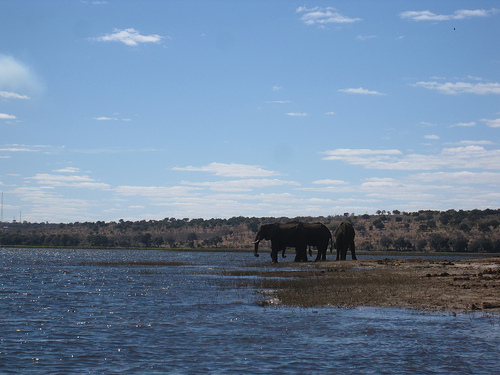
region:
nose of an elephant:
[249, 238, 264, 267]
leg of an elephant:
[263, 242, 280, 267]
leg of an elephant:
[288, 244, 315, 264]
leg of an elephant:
[308, 240, 333, 268]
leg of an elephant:
[334, 244, 354, 259]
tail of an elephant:
[322, 227, 342, 254]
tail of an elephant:
[306, 247, 316, 257]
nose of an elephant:
[329, 238, 337, 261]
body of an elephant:
[309, 212, 339, 250]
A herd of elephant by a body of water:
[235, 210, 362, 275]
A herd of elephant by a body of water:
[247, 216, 359, 271]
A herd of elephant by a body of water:
[240, 210, 359, 269]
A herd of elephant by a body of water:
[242, 212, 365, 272]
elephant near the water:
[233, 193, 352, 277]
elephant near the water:
[248, 205, 350, 275]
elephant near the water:
[241, 199, 368, 267]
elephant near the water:
[231, 200, 361, 282]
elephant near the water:
[244, 204, 362, 276]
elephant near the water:
[243, 194, 364, 269]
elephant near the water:
[242, 217, 342, 272]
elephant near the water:
[328, 213, 354, 258]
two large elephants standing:
[243, 219, 362, 265]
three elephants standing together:
[260, 213, 360, 265]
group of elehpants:
[247, 218, 369, 265]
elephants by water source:
[233, 210, 333, 267]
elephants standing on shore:
[245, 210, 373, 275]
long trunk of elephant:
[247, 234, 262, 256]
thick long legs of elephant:
[258, 250, 290, 270]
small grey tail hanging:
[304, 243, 323, 255]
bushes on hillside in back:
[116, 210, 213, 255]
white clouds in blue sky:
[1, 13, 169, 122]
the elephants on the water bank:
[247, 216, 362, 270]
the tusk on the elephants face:
[248, 236, 263, 244]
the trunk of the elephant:
[250, 239, 262, 259]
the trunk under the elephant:
[276, 244, 290, 261]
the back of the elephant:
[333, 220, 356, 260]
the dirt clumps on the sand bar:
[418, 257, 498, 308]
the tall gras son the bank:
[211, 268, 387, 301]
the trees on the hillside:
[382, 205, 494, 257]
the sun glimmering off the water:
[10, 270, 126, 358]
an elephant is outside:
[276, 204, 319, 289]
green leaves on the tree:
[161, 214, 173, 222]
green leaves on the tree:
[438, 238, 448, 258]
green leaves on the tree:
[471, 217, 498, 262]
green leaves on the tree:
[79, 232, 139, 244]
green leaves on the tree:
[191, 230, 246, 257]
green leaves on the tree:
[382, 206, 420, 236]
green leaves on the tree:
[413, 193, 443, 222]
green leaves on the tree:
[452, 210, 458, 223]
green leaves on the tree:
[433, 201, 449, 224]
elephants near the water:
[246, 212, 361, 262]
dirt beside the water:
[260, 260, 497, 310]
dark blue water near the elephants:
[1, 247, 498, 374]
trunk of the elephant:
[250, 238, 262, 255]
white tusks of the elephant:
[253, 239, 264, 246]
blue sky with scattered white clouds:
[2, 3, 498, 213]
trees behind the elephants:
[5, 205, 499, 247]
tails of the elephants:
[306, 223, 333, 255]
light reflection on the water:
[15, 242, 167, 365]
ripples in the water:
[19, 243, 350, 369]